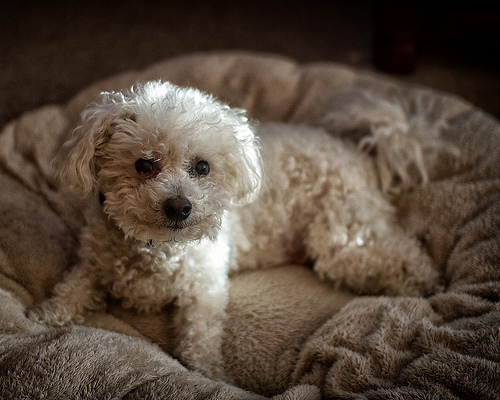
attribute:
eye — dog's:
[130, 155, 158, 177]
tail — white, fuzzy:
[329, 91, 464, 200]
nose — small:
[161, 190, 198, 227]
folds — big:
[303, 136, 467, 398]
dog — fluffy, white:
[30, 77, 433, 371]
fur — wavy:
[121, 93, 211, 130]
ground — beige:
[376, 129, 402, 170]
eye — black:
[192, 151, 214, 175]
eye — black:
[129, 147, 158, 182]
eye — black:
[188, 158, 208, 174]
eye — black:
[133, 158, 159, 174]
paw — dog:
[381, 255, 441, 300]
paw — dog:
[166, 337, 233, 382]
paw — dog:
[25, 295, 96, 326]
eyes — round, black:
[133, 154, 212, 179]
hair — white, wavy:
[191, 106, 225, 141]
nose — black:
[163, 180, 208, 218]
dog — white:
[27, 76, 462, 349]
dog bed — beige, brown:
[2, 45, 498, 398]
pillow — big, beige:
[1, 51, 498, 398]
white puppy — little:
[10, 86, 445, 367]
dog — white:
[27, 84, 295, 374]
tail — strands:
[346, 82, 453, 177]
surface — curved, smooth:
[22, 326, 493, 395]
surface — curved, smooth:
[423, 97, 493, 388]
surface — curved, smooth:
[257, 61, 348, 123]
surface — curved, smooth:
[9, 119, 53, 277]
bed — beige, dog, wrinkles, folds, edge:
[8, 52, 494, 389]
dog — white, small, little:
[17, 76, 459, 390]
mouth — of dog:
[127, 176, 225, 226]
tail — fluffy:
[320, 81, 460, 189]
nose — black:
[160, 193, 190, 224]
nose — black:
[161, 193, 192, 219]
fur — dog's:
[138, 147, 158, 162]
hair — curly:
[71, 68, 431, 331]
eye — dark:
[188, 158, 212, 177]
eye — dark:
[134, 153, 166, 174]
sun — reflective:
[143, 82, 266, 276]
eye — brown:
[189, 158, 211, 179]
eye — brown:
[134, 156, 166, 180]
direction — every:
[352, 68, 492, 218]